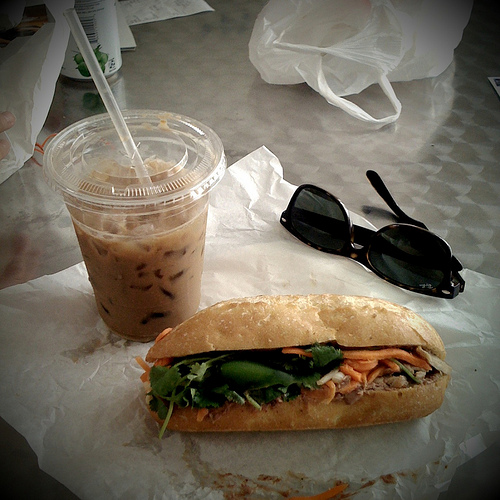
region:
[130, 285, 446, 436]
a small sub sandwich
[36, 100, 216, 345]
Cup of iced coffee with straw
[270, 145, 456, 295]
sunglasses on the table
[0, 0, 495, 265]
beige patterned table top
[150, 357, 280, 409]
dark leafy vegetable on one end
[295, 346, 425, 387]
pieces of shredded carrot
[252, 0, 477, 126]
empty white plastic bag with handles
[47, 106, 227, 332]
cup and lid are clear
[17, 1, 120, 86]
a white and green aluminum can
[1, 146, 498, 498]
food sits on white waxed paper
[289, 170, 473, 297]
Black glasses on table.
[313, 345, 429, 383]
Orange carrots on sandwich.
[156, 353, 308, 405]
Green lettuce on sandwich.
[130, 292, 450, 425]
Whole sandwich on wrapper.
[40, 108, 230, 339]
Iced drink in clear cup.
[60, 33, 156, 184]
Plastic straw in cup.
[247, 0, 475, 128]
White plastic bag on table.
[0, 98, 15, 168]
Person's fingers on sack.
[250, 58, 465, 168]
Reflection of bag on table.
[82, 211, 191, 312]
Ice cubes in coffee drink.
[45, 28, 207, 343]
an ice drink in a plastic cup with a lid and straw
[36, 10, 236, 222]
a straw in a plastic lid of a cup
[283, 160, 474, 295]
a pair of sunglasses on a table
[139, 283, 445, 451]
a sandwich on a piece of paper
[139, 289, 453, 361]
the bun of a sandwich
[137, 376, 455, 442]
the bun of a sandwich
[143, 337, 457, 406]
the makings of a sandwich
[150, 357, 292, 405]
lettuce on a sandwich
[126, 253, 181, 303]
the ice in a drink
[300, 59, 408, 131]
the handle of a plastic bag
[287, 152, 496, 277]
sunglasses on the wrapper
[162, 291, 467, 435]
sandwich on the wrapper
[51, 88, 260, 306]
drink on the wrapper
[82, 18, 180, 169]
cup has a straw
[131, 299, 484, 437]
sandwich is in a roll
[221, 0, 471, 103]
white bag on the counter top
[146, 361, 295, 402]
lettuce on the sandwich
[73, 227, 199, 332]
ice cubes in the drink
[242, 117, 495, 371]
wrapper is on the counter top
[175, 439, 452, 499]
sauce on the wrapper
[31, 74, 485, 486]
picture of a lunchtime meal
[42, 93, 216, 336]
ice coffee in a plastic cup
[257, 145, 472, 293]
black sunglasses on top of white wax paper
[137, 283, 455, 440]
sandwich in a white bun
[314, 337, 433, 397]
shredded cheddar cheese on sandwich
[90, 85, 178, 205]
clear plastic straw in coffee cup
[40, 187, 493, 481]
white wax paper under sandwich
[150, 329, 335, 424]
green lettuce in sandwich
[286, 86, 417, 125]
handle of white plastic bag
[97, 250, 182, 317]
chunks of ice in the coffee